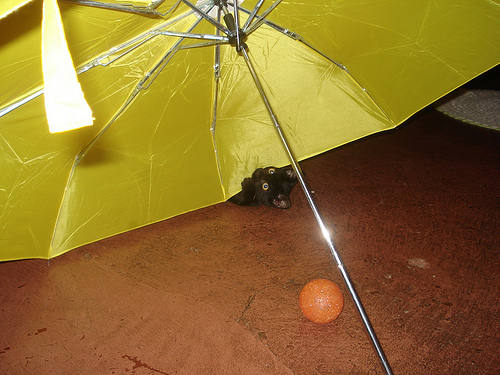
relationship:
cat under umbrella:
[232, 162, 305, 211] [1, 1, 499, 264]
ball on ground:
[294, 274, 348, 326] [4, 113, 500, 373]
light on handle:
[312, 216, 345, 250] [242, 43, 389, 371]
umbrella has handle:
[1, 1, 499, 264] [242, 43, 389, 371]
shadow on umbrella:
[74, 134, 113, 172] [1, 1, 499, 264]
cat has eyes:
[232, 162, 305, 211] [264, 160, 278, 196]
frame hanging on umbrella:
[40, 0, 95, 134] [1, 1, 499, 264]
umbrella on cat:
[1, 1, 499, 264] [232, 162, 305, 211]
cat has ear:
[232, 162, 305, 211] [284, 166, 305, 183]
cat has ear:
[232, 162, 305, 211] [272, 192, 293, 211]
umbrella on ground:
[1, 1, 499, 264] [4, 113, 500, 373]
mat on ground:
[434, 82, 498, 131] [4, 113, 500, 373]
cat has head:
[232, 162, 305, 211] [252, 162, 289, 207]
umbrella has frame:
[1, 1, 499, 264] [1, 7, 362, 148]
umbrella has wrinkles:
[1, 1, 499, 264] [3, 26, 193, 219]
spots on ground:
[4, 320, 164, 373] [4, 113, 500, 373]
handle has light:
[242, 43, 389, 371] [312, 216, 345, 250]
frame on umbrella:
[40, 0, 95, 134] [1, 1, 499, 264]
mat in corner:
[434, 82, 498, 131] [324, 2, 495, 196]